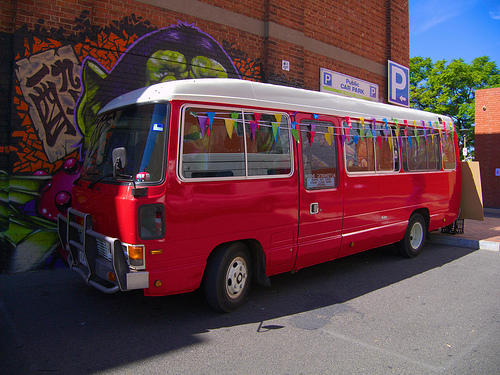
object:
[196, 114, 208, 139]
flag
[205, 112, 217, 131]
flag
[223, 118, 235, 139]
flag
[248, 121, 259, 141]
flag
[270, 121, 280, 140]
flag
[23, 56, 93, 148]
writing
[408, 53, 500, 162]
tree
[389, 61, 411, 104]
sign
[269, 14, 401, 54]
wall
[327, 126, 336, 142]
flag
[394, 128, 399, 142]
flag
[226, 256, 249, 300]
rim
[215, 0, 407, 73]
bricks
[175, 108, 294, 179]
windows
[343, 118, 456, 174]
windows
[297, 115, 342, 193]
windows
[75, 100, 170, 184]
windows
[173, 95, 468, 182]
white frame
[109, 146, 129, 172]
mirror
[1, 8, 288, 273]
grafitti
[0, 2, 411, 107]
brick wall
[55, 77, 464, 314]
bus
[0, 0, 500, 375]
picture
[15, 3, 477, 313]
combi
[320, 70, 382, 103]
sign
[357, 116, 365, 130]
flags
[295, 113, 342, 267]
door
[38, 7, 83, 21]
brick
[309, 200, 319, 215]
handle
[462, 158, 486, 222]
brown board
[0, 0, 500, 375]
outdoors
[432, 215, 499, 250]
sidewalk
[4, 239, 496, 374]
parking area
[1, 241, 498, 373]
road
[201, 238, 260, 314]
tire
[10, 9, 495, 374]
day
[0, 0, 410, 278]
building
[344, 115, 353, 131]
flags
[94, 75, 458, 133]
top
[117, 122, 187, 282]
side